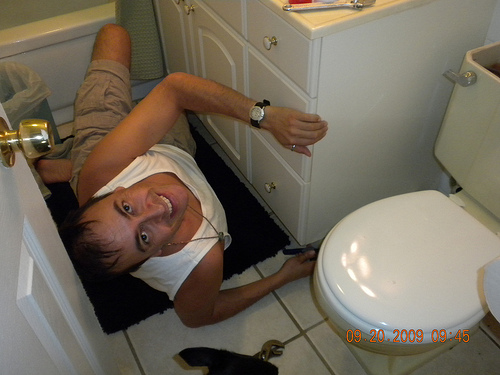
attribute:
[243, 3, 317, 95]
drawer — beneath the sink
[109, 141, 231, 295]
tank top — white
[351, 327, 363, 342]
number — orange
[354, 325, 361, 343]
number — orange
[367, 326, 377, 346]
number — orange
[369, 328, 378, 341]
number — orange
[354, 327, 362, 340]
number — orange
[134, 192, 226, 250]
necklace — silver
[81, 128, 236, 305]
tank top — white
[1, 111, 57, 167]
door knob — gold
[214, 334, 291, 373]
wrench — silver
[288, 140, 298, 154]
ring — silver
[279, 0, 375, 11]
wrench — silver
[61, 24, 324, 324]
man — watch.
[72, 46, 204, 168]
shorts — khaki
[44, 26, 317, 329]
man — bathroom floor